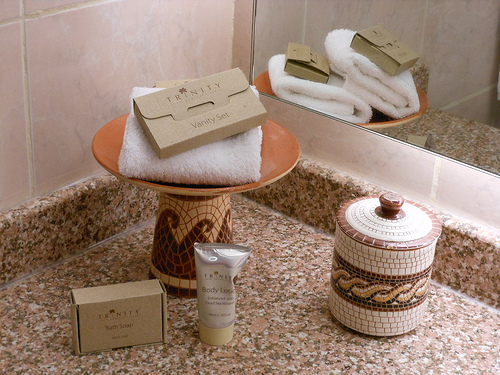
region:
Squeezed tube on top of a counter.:
[193, 231, 254, 355]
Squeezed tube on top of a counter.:
[93, 23, 148, 58]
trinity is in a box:
[146, 78, 267, 155]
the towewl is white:
[119, 136, 269, 176]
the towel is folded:
[124, 145, 254, 176]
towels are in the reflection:
[276, 45, 428, 129]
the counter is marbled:
[248, 238, 320, 347]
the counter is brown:
[270, 269, 315, 359]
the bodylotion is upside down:
[188, 245, 243, 344]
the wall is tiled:
[16, 111, 84, 182]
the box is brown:
[63, 281, 172, 355]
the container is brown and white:
[334, 198, 446, 345]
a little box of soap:
[56, 263, 178, 358]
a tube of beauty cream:
[181, 228, 251, 351]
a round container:
[317, 179, 444, 342]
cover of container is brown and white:
[327, 185, 445, 255]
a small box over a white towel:
[110, 59, 272, 190]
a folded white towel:
[114, 69, 276, 189]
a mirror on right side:
[240, 3, 498, 198]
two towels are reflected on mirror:
[254, 18, 425, 129]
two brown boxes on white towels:
[279, 13, 427, 94]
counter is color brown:
[1, 151, 496, 373]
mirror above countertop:
[252, 8, 492, 177]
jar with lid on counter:
[323, 188, 436, 338]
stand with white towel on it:
[90, 108, 287, 287]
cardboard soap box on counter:
[55, 278, 165, 346]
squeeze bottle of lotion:
[188, 243, 250, 343]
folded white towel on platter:
[126, 75, 259, 177]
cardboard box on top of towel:
[133, 67, 265, 148]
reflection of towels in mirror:
[255, 23, 420, 126]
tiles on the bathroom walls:
[10, 8, 482, 204]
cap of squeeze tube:
[200, 324, 232, 346]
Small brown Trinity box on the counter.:
[64, 277, 170, 358]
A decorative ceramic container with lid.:
[328, 190, 443, 337]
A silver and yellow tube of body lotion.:
[191, 240, 251, 347]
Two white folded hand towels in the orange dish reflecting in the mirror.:
[266, 27, 418, 124]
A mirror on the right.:
[251, 1, 498, 173]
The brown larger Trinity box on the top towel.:
[130, 65, 267, 155]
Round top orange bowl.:
[90, 111, 300, 196]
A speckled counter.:
[2, 193, 499, 372]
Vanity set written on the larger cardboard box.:
[189, 108, 232, 130]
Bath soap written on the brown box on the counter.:
[102, 320, 135, 330]